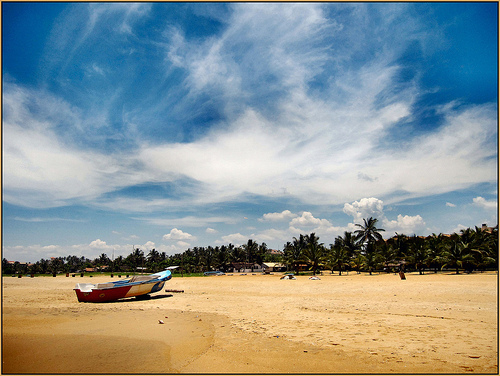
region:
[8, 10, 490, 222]
blue sky with wispy clouds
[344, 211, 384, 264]
tall green palm tree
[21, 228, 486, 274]
row of trees along the beach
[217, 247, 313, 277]
tan house along the beach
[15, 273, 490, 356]
brown sandy expanse of beach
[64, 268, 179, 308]
boat up on the sand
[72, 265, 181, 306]
tricolored boat propped up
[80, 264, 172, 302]
red, white and blue boat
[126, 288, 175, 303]
shadow cast by boat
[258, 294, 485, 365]
footprints in the sand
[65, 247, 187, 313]
a red and blue boat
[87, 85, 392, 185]
whispy clouds in the sky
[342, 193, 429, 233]
small, white, fluffy clouds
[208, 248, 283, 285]
a brown and white building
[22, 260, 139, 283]
a grassy park near the beach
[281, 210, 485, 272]
a few palm trees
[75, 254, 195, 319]
boat pulled up on the beach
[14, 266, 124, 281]
a row of cylinder shapes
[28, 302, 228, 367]
water marks on sand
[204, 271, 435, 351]
golden sand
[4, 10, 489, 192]
wispy clouds in a blue sky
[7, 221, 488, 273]
dense treeline along the beach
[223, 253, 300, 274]
tan house in the trees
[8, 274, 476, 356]
brown sandy stretch of beach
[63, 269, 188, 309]
boat resting on the sand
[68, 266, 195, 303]
red back of boat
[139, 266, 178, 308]
blue front of boat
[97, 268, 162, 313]
white stripe on boat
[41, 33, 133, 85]
Sky is blue color.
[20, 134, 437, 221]
Clouds are white color.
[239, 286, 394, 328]
Sand is brown color.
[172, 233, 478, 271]
Trees are green color.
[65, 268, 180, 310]
One boat is seen.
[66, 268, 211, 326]
Boat is red,white and blue.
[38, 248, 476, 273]
Trees are found behind the sand.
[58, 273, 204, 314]
Boat is standing in the sand.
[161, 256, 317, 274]
buildings are seen behind the trees.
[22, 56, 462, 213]
Clouds are scattered in the sky.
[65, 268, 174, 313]
this is a motor boat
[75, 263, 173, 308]
the motor boat is parked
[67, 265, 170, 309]
the motor boat is red and white in color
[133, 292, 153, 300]
a stone is under the motor boat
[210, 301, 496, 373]
sand is allover the place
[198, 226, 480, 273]
trees are in a straight line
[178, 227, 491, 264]
the trees are green in color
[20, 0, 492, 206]
the sky has white clouds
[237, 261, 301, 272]
these are houses on the farthest part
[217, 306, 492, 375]
the sand is brown in color